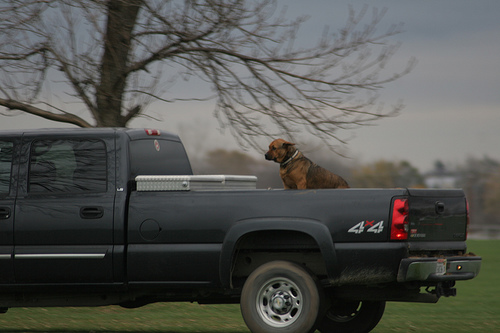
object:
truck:
[0, 127, 484, 332]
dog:
[264, 139, 350, 190]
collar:
[280, 150, 299, 167]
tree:
[0, 0, 418, 160]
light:
[390, 199, 409, 240]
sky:
[392, 1, 499, 162]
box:
[135, 175, 258, 193]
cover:
[140, 220, 160, 240]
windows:
[29, 138, 108, 194]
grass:
[370, 240, 499, 333]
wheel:
[239, 259, 328, 332]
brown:
[289, 166, 306, 185]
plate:
[435, 259, 447, 275]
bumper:
[396, 252, 482, 282]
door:
[12, 131, 116, 287]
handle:
[81, 207, 102, 219]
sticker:
[153, 139, 160, 152]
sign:
[347, 220, 385, 234]